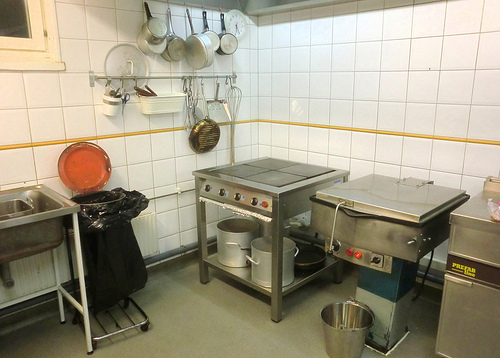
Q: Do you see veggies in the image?
A: No, there are no veggies.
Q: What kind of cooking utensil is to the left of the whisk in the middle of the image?
A: The cooking utensil is a skillet.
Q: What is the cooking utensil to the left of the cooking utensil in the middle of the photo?
A: The cooking utensil is a skillet.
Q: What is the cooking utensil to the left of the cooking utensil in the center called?
A: The cooking utensil is a skillet.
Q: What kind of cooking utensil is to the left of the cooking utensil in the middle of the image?
A: The cooking utensil is a skillet.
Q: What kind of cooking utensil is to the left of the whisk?
A: The cooking utensil is a skillet.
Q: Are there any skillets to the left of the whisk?
A: Yes, there is a skillet to the left of the whisk.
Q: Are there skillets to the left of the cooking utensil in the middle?
A: Yes, there is a skillet to the left of the whisk.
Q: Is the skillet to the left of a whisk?
A: Yes, the skillet is to the left of a whisk.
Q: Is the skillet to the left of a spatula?
A: No, the skillet is to the left of a whisk.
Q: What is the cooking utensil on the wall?
A: The cooking utensil is a skillet.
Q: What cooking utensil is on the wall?
A: The cooking utensil is a skillet.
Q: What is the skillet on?
A: The skillet is on the wall.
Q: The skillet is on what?
A: The skillet is on the wall.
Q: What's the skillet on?
A: The skillet is on the wall.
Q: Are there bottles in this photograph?
A: No, there are no bottles.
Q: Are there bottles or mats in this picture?
A: No, there are no bottles or mats.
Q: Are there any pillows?
A: No, there are no pillows.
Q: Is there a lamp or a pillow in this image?
A: No, there are no pillows or lamps.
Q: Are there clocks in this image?
A: Yes, there is a clock.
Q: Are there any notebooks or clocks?
A: Yes, there is a clock.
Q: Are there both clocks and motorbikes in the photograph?
A: No, there is a clock but no motorcycles.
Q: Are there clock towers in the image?
A: No, there are no clock towers.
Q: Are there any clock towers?
A: No, there are no clock towers.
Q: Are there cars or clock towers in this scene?
A: No, there are no clock towers or cars.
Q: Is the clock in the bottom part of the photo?
A: No, the clock is in the top of the image.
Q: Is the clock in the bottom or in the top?
A: The clock is in the top of the image.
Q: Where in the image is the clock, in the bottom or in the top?
A: The clock is in the top of the image.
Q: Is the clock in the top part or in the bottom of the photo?
A: The clock is in the top of the image.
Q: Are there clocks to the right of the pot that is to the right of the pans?
A: Yes, there is a clock to the right of the pot.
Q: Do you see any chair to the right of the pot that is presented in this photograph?
A: No, there is a clock to the right of the pot.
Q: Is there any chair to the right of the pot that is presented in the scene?
A: No, there is a clock to the right of the pot.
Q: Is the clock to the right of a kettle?
A: No, the clock is to the right of the pot.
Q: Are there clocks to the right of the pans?
A: Yes, there is a clock to the right of the pans.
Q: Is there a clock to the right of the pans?
A: Yes, there is a clock to the right of the pans.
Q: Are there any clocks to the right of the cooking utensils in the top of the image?
A: Yes, there is a clock to the right of the pans.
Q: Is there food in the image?
A: No, there is no food.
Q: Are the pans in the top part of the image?
A: Yes, the pans are in the top of the image.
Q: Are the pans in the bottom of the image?
A: No, the pans are in the top of the image.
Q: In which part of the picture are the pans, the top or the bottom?
A: The pans are in the top of the image.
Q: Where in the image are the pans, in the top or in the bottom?
A: The pans are in the top of the image.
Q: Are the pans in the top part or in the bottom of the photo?
A: The pans are in the top of the image.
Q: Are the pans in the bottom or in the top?
A: The pans are in the top of the image.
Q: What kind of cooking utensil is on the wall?
A: The cooking utensils are pans.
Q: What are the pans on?
A: The pans are on the wall.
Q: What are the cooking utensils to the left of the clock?
A: The cooking utensils are pans.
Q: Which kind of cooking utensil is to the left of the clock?
A: The cooking utensils are pans.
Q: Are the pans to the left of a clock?
A: Yes, the pans are to the left of a clock.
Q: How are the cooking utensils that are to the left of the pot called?
A: The cooking utensils are pans.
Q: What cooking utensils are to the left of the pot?
A: The cooking utensils are pans.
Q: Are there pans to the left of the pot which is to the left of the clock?
A: Yes, there are pans to the left of the pot.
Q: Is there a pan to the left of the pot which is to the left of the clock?
A: Yes, there are pans to the left of the pot.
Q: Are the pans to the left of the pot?
A: Yes, the pans are to the left of the pot.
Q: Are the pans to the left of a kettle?
A: No, the pans are to the left of the pot.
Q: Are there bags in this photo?
A: Yes, there is a bag.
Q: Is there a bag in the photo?
A: Yes, there is a bag.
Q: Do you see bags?
A: Yes, there is a bag.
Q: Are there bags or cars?
A: Yes, there is a bag.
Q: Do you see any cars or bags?
A: Yes, there is a bag.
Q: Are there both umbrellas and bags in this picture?
A: No, there is a bag but no umbrellas.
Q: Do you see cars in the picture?
A: No, there are no cars.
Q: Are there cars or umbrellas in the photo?
A: No, there are no cars or umbrellas.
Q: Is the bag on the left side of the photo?
A: Yes, the bag is on the left of the image.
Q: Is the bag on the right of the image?
A: No, the bag is on the left of the image.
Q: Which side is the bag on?
A: The bag is on the left of the image.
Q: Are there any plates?
A: Yes, there is a plate.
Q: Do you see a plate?
A: Yes, there is a plate.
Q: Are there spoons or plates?
A: Yes, there is a plate.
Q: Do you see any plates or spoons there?
A: Yes, there is a plate.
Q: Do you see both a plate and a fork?
A: No, there is a plate but no forks.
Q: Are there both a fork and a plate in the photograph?
A: No, there is a plate but no forks.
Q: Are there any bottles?
A: No, there are no bottles.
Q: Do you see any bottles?
A: No, there are no bottles.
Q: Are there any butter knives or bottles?
A: No, there are no bottles or butter knives.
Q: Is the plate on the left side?
A: Yes, the plate is on the left of the image.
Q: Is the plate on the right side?
A: No, the plate is on the left of the image.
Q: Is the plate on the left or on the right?
A: The plate is on the left of the image.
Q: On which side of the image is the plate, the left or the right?
A: The plate is on the left of the image.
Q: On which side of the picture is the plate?
A: The plate is on the left of the image.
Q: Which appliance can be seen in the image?
A: The appliance is a stove.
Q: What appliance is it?
A: The appliance is a stove.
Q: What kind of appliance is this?
A: This is a stove.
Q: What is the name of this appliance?
A: This is a stove.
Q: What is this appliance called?
A: This is a stove.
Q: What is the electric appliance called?
A: The appliance is a stove.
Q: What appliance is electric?
A: The appliance is a stove.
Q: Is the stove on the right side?
A: Yes, the stove is on the right of the image.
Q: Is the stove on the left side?
A: No, the stove is on the right of the image.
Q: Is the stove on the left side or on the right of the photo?
A: The stove is on the right of the image.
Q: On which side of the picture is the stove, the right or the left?
A: The stove is on the right of the image.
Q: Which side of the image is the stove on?
A: The stove is on the right of the image.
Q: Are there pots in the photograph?
A: Yes, there is a pot.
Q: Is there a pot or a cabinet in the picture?
A: Yes, there is a pot.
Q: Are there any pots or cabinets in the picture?
A: Yes, there is a pot.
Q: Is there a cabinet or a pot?
A: Yes, there is a pot.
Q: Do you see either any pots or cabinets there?
A: Yes, there is a pot.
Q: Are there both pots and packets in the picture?
A: No, there is a pot but no packets.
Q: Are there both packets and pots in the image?
A: No, there is a pot but no packets.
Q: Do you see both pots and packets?
A: No, there is a pot but no packets.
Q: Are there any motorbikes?
A: No, there are no motorbikes.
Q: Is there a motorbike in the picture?
A: No, there are no motorcycles.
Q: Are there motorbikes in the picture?
A: No, there are no motorbikes.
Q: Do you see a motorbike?
A: No, there are no motorcycles.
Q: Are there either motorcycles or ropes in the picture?
A: No, there are no motorcycles or ropes.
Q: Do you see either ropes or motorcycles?
A: No, there are no motorcycles or ropes.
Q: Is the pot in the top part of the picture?
A: Yes, the pot is in the top of the image.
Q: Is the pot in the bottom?
A: No, the pot is in the top of the image.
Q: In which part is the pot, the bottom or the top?
A: The pot is in the top of the image.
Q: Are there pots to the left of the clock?
A: Yes, there is a pot to the left of the clock.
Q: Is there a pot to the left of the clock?
A: Yes, there is a pot to the left of the clock.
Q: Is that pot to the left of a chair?
A: No, the pot is to the left of the clock.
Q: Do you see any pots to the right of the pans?
A: Yes, there is a pot to the right of the pans.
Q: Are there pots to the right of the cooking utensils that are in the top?
A: Yes, there is a pot to the right of the pans.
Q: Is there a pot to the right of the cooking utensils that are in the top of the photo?
A: Yes, there is a pot to the right of the pans.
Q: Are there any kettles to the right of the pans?
A: No, there is a pot to the right of the pans.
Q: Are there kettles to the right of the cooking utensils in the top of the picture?
A: No, there is a pot to the right of the pans.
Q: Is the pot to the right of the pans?
A: Yes, the pot is to the right of the pans.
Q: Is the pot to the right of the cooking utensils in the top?
A: Yes, the pot is to the right of the pans.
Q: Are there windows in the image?
A: Yes, there is a window.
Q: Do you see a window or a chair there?
A: Yes, there is a window.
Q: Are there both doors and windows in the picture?
A: No, there is a window but no doors.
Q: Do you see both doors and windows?
A: No, there is a window but no doors.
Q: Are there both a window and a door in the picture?
A: No, there is a window but no doors.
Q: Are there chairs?
A: No, there are no chairs.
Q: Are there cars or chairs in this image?
A: No, there are no chairs or cars.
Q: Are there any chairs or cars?
A: No, there are no chairs or cars.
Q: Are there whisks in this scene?
A: Yes, there is a whisk.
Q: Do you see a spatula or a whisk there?
A: Yes, there is a whisk.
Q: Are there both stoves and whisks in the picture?
A: Yes, there are both a whisk and a stove.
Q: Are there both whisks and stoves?
A: Yes, there are both a whisk and a stove.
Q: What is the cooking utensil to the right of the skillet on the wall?
A: The cooking utensil is a whisk.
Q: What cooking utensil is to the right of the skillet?
A: The cooking utensil is a whisk.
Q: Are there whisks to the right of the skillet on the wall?
A: Yes, there is a whisk to the right of the skillet.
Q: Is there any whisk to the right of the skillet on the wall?
A: Yes, there is a whisk to the right of the skillet.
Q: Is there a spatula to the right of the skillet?
A: No, there is a whisk to the right of the skillet.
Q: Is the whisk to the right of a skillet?
A: Yes, the whisk is to the right of a skillet.